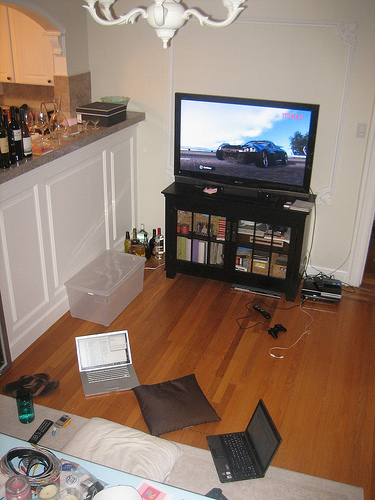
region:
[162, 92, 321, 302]
flat screen television on a television cabinet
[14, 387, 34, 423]
a partially filled green water bottle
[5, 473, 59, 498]
white candle beside a pink candle with a lid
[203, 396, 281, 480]
black laptop computer that is on the floor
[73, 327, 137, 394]
a white laptop computer on the floor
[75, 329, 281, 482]
dark brown throw pillow on the floor between laptops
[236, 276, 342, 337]
game player with an attached game controller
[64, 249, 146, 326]
a large empty clear plastic lidded bin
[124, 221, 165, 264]
liquor bottles on the ground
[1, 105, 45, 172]
bottles and wine glasses on a counter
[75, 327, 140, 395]
A silver laptop computer on the floor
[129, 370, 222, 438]
A square dark brown pillow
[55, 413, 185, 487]
A white pillow on the rug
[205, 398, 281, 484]
A black laptop computer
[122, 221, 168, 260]
Bottles sitting in the corner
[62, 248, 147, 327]
A large plastic bin on the floor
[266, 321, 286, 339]
A black video game controller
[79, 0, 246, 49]
A white chandelier in the ceiling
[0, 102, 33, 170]
Bottles of wine on the counter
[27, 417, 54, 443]
A black remote control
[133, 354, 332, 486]
this is a laptop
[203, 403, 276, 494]
the laptop is black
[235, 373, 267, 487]
this is a screen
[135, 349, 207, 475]
this is a pillow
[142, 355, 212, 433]
the pillow is brown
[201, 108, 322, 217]
this is a television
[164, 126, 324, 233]
the tv is on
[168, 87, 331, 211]
large flat screen TV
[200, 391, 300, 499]
black laptop sittingon floor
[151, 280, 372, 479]
medium brown hard wood flooring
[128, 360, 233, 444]
brown pillow on floor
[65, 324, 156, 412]
sivler laptop sitting on floor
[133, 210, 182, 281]
liquor bottles sitting in corner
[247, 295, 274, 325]
black remote control sitting on floor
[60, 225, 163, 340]
clear plastic storage bin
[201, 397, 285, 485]
a black laptop on the floor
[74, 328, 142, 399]
silver laptop on a wooden floor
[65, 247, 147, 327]
a clear storage box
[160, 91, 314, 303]
TV on a TV stand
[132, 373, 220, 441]
a brown pillow with on a wooden floor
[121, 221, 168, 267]
alcohol bottles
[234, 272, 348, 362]
gaming machine and controllers on a wooden floor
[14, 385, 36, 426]
green remote controller on a carpet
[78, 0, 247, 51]
white lighting fixture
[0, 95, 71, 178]
bottles and glasses on a granite counter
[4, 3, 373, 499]
Living room area with partial view of kitchen shown.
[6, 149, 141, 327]
White, etched counter, separating rooms, near plastic box.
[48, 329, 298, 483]
Polished wood and carpeting, showing 2 open laptops and cushion.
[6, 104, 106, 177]
Bottles and wine glasses on marble, countertop.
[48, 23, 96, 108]
Decorative wall column.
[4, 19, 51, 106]
White cabinetry, giving evidence of low light and kitchen area.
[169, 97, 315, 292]
Neatly housed items in entertainment area, below television, showing car.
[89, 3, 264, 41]
White chandelier, on ceiling.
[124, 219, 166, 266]
Long-necked bottles in corner of room.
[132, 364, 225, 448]
pillow is on the floor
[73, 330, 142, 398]
laptop is color grey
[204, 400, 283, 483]
laptop is color black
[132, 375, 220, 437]
pillow is color brown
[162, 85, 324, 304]
tv is on the tv stand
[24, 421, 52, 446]
remote is on the carpet